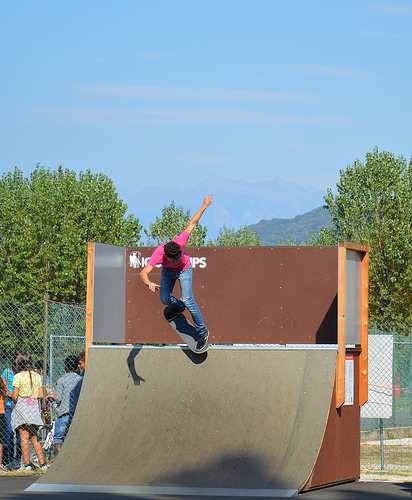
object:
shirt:
[148, 229, 192, 271]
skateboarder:
[138, 194, 212, 353]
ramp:
[24, 239, 369, 497]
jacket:
[9, 395, 45, 429]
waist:
[16, 390, 40, 403]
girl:
[8, 353, 50, 476]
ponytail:
[18, 354, 35, 388]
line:
[25, 473, 301, 499]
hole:
[180, 291, 188, 307]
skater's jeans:
[158, 264, 208, 343]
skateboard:
[164, 306, 210, 354]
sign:
[344, 350, 357, 408]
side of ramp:
[299, 237, 371, 490]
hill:
[234, 192, 336, 246]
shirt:
[11, 369, 43, 398]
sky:
[0, 1, 412, 248]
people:
[2, 353, 85, 473]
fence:
[0, 296, 411, 480]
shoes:
[162, 297, 209, 353]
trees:
[2, 148, 412, 373]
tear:
[178, 293, 191, 307]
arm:
[138, 248, 162, 293]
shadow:
[126, 340, 147, 388]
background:
[0, 0, 411, 333]